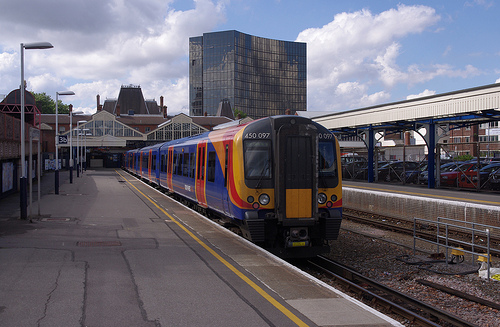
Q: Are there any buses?
A: No, there are no buses.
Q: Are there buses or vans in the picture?
A: No, there are no buses or vans.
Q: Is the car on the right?
A: Yes, the car is on the right of the image.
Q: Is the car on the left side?
A: No, the car is on the right of the image.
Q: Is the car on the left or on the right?
A: The car is on the right of the image.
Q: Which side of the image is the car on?
A: The car is on the right of the image.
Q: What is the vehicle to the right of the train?
A: The vehicle is a car.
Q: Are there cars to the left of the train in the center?
A: No, the car is to the right of the train.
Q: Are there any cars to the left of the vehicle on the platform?
A: No, the car is to the right of the train.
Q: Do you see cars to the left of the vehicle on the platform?
A: No, the car is to the right of the train.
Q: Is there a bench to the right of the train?
A: No, there is a car to the right of the train.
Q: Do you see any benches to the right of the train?
A: No, there is a car to the right of the train.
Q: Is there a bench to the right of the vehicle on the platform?
A: No, there is a car to the right of the train.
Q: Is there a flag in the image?
A: No, there are no flags.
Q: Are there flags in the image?
A: No, there are no flags.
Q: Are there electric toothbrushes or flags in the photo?
A: No, there are no flags or electric toothbrushes.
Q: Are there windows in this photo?
A: Yes, there is a window.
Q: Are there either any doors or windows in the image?
A: Yes, there is a window.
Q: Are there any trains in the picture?
A: Yes, there is a train.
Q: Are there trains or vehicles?
A: Yes, there is a train.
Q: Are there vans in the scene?
A: No, there are no vans.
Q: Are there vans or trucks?
A: No, there are no vans or trucks.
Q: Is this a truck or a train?
A: This is a train.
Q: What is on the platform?
A: The train is on the platform.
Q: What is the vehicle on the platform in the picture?
A: The vehicle is a train.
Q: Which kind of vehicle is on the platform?
A: The vehicle is a train.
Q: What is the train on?
A: The train is on the platform.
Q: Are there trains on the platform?
A: Yes, there is a train on the platform.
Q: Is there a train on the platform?
A: Yes, there is a train on the platform.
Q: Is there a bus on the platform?
A: No, there is a train on the platform.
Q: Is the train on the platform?
A: Yes, the train is on the platform.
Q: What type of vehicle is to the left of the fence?
A: The vehicle is a train.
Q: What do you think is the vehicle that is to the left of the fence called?
A: The vehicle is a train.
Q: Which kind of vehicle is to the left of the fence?
A: The vehicle is a train.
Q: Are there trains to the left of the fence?
A: Yes, there is a train to the left of the fence.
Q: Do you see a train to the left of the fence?
A: Yes, there is a train to the left of the fence.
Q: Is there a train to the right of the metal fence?
A: No, the train is to the left of the fence.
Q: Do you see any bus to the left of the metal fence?
A: No, there is a train to the left of the fence.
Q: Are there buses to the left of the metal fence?
A: No, there is a train to the left of the fence.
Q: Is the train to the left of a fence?
A: Yes, the train is to the left of a fence.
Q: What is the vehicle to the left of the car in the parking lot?
A: The vehicle is a train.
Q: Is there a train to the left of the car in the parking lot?
A: Yes, there is a train to the left of the car.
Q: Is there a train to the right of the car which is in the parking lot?
A: No, the train is to the left of the car.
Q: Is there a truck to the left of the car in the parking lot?
A: No, there is a train to the left of the car.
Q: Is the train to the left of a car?
A: Yes, the train is to the left of a car.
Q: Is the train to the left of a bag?
A: No, the train is to the left of a car.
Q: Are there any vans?
A: No, there are no vans.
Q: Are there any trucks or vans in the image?
A: No, there are no vans or trucks.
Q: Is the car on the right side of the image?
A: Yes, the car is on the right of the image.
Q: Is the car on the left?
A: No, the car is on the right of the image.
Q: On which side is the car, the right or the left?
A: The car is on the right of the image.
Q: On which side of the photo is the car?
A: The car is on the right of the image.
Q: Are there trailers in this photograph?
A: No, there are no trailers.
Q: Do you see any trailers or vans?
A: No, there are no trailers or vans.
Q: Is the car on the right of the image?
A: Yes, the car is on the right of the image.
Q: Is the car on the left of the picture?
A: No, the car is on the right of the image.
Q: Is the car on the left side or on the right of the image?
A: The car is on the right of the image.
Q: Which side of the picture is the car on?
A: The car is on the right of the image.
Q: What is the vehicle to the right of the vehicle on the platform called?
A: The vehicle is a car.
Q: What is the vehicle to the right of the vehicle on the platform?
A: The vehicle is a car.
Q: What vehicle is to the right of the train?
A: The vehicle is a car.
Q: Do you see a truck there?
A: No, there are no trucks.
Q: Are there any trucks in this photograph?
A: No, there are no trucks.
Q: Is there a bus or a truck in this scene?
A: No, there are no trucks or buses.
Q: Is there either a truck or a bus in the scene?
A: No, there are no trucks or buses.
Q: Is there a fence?
A: Yes, there is a fence.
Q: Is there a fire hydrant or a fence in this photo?
A: Yes, there is a fence.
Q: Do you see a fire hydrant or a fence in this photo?
A: Yes, there is a fence.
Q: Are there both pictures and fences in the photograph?
A: No, there is a fence but no pictures.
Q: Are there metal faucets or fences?
A: Yes, there is a metal fence.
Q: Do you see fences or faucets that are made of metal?
A: Yes, the fence is made of metal.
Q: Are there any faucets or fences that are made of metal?
A: Yes, the fence is made of metal.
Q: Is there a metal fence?
A: Yes, there is a fence that is made of metal.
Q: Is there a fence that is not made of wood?
A: Yes, there is a fence that is made of metal.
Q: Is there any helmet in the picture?
A: No, there are no helmets.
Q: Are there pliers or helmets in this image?
A: No, there are no helmets or pliers.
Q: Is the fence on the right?
A: Yes, the fence is on the right of the image.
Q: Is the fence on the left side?
A: No, the fence is on the right of the image.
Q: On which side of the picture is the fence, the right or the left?
A: The fence is on the right of the image.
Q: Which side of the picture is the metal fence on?
A: The fence is on the right of the image.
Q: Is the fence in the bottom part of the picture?
A: Yes, the fence is in the bottom of the image.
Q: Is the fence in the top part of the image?
A: No, the fence is in the bottom of the image.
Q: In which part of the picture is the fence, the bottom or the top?
A: The fence is in the bottom of the image.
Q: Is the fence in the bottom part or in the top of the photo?
A: The fence is in the bottom of the image.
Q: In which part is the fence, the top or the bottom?
A: The fence is in the bottom of the image.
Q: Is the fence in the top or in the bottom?
A: The fence is in the bottom of the image.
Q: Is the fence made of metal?
A: Yes, the fence is made of metal.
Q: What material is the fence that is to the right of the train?
A: The fence is made of metal.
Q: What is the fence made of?
A: The fence is made of metal.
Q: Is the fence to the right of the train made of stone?
A: No, the fence is made of metal.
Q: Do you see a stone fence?
A: No, there is a fence but it is made of metal.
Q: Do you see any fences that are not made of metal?
A: No, there is a fence but it is made of metal.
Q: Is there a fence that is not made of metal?
A: No, there is a fence but it is made of metal.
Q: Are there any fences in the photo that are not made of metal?
A: No, there is a fence but it is made of metal.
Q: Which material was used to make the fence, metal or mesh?
A: The fence is made of metal.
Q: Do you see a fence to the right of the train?
A: Yes, there is a fence to the right of the train.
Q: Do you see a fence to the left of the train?
A: No, the fence is to the right of the train.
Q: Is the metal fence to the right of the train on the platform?
A: Yes, the fence is to the right of the train.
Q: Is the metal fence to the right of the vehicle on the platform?
A: Yes, the fence is to the right of the train.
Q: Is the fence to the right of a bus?
A: No, the fence is to the right of the train.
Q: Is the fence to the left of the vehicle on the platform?
A: No, the fence is to the right of the train.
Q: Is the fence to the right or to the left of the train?
A: The fence is to the right of the train.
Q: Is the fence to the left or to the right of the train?
A: The fence is to the right of the train.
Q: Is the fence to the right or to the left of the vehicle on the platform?
A: The fence is to the right of the train.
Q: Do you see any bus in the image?
A: No, there are no buses.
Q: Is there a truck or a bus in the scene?
A: No, there are no buses or trucks.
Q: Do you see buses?
A: No, there are no buses.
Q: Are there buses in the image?
A: No, there are no buses.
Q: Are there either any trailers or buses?
A: No, there are no buses or trailers.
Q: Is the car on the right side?
A: Yes, the car is on the right of the image.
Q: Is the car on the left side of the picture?
A: No, the car is on the right of the image.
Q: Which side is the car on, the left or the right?
A: The car is on the right of the image.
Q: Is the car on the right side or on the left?
A: The car is on the right of the image.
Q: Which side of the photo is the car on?
A: The car is on the right of the image.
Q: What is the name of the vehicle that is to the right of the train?
A: The vehicle is a car.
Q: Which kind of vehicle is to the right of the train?
A: The vehicle is a car.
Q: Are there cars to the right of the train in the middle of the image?
A: Yes, there is a car to the right of the train.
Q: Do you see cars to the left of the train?
A: No, the car is to the right of the train.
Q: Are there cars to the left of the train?
A: No, the car is to the right of the train.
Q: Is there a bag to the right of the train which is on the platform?
A: No, there is a car to the right of the train.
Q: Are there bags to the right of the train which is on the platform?
A: No, there is a car to the right of the train.